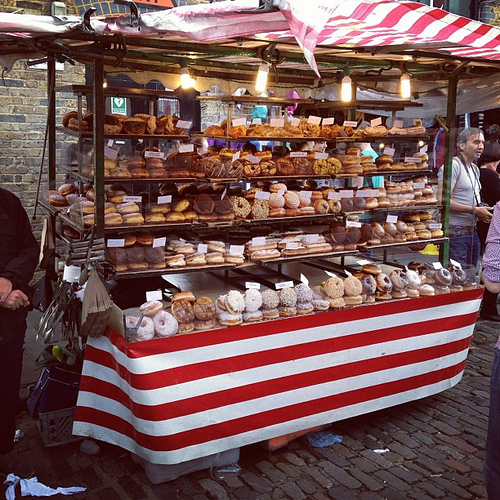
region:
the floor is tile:
[408, 463, 460, 497]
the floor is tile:
[314, 478, 354, 498]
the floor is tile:
[350, 448, 407, 469]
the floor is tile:
[339, 463, 376, 498]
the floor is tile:
[342, 455, 404, 497]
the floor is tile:
[339, 453, 386, 482]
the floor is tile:
[337, 441, 399, 473]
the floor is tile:
[359, 461, 401, 488]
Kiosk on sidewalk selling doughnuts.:
[42, 6, 489, 476]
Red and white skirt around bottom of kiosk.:
[81, 301, 491, 472]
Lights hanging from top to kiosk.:
[165, 52, 425, 105]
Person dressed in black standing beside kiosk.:
[1, 183, 42, 462]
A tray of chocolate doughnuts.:
[330, 221, 376, 263]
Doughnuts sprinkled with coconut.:
[217, 286, 272, 328]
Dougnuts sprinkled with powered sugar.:
[128, 301, 180, 343]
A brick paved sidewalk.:
[364, 426, 484, 496]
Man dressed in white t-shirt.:
[433, 153, 487, 225]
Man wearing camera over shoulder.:
[461, 149, 491, 216]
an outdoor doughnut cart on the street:
[43, 37, 467, 482]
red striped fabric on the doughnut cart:
[96, 336, 456, 383]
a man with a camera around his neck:
[438, 125, 493, 269]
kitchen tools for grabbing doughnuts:
[33, 273, 80, 350]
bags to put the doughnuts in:
[78, 269, 117, 342]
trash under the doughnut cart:
[302, 430, 346, 448]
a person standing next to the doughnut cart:
[1, 180, 42, 454]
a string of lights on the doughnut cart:
[106, 32, 440, 109]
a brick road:
[3, 287, 487, 498]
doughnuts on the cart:
[113, 256, 495, 343]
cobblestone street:
[360, 424, 476, 493]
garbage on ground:
[292, 412, 396, 464]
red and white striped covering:
[83, 329, 480, 416]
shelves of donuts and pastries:
[58, 93, 470, 311]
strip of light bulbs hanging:
[106, 41, 454, 113]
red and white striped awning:
[147, 3, 495, 140]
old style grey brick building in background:
[2, 72, 79, 230]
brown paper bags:
[75, 256, 112, 342]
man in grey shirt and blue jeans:
[437, 122, 494, 289]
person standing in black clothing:
[0, 163, 42, 487]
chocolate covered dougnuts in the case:
[174, 193, 239, 218]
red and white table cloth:
[79, 329, 463, 442]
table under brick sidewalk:
[310, 408, 495, 498]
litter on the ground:
[0, 469, 95, 496]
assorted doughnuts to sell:
[128, 89, 482, 348]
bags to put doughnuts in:
[62, 265, 112, 347]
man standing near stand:
[451, 121, 484, 268]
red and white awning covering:
[139, 4, 499, 59]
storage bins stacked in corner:
[38, 369, 81, 454]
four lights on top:
[145, 71, 419, 95]